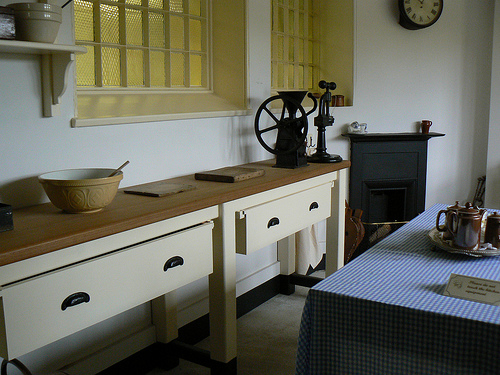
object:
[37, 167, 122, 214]
bowl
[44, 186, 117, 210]
design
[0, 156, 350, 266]
top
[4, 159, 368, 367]
buffet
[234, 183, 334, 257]
drawer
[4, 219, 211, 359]
drawer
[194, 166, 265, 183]
board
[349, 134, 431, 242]
fireplace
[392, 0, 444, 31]
clock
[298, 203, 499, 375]
tablecloth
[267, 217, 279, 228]
handle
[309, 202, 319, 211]
handle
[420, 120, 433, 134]
cup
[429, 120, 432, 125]
handle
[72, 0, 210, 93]
window